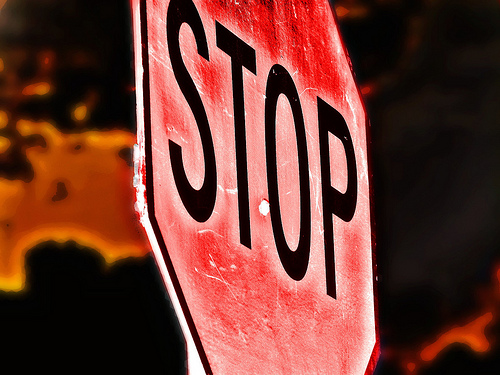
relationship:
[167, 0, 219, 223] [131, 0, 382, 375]
black s on a stop sign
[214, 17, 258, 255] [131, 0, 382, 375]
black t on a stop sign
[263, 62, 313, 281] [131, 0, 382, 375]
black o on a stop sign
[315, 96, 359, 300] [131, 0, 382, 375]
black p on a stop sign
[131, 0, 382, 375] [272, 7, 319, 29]
stop sign that bright red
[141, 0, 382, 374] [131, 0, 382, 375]
black line on perimeter of stop sign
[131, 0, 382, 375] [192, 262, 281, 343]
stop sign that black and orange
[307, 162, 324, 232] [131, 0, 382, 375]
scratches on a stop sign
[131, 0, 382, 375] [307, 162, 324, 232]
stop sign with scratches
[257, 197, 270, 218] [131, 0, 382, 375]
hole in a stop sign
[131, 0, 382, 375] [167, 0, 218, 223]
sign that says black s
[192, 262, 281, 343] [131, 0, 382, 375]
black and orange colored stop sign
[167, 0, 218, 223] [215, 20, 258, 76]
black s that are thick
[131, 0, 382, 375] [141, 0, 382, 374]
stop sign with a black line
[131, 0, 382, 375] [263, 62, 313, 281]
stop sign with a black o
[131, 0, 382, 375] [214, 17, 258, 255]
stop sign with a black t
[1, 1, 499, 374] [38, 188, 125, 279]
background that orange and black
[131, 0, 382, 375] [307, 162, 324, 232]
stop sign with white scratches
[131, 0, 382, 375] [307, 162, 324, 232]
stop sign with some scratches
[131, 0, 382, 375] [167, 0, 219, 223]
stop sign with a black s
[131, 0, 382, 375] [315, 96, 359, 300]
stop sign with a black p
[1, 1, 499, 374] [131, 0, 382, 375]
background of a stop sign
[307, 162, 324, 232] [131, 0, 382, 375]
scratches on a sign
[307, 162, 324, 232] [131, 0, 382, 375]
scratches all over a stop sign